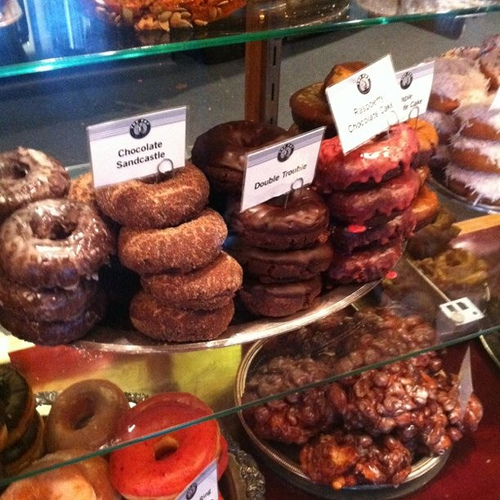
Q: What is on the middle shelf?
A: Donuts.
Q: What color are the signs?
A: White.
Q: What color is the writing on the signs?
A: Black.